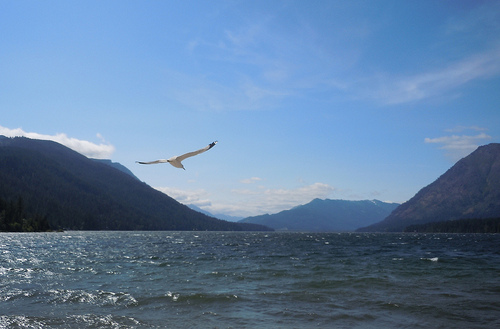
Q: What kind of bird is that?
A: A seagull.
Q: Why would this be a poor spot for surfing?
A: The waves are very small.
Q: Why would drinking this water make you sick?
A: It is saltwater.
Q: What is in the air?
A: A bird.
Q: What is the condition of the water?
A: Calm.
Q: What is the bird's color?
A: White.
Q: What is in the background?
A: Mountains.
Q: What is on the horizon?
A: Mountain.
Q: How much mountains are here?
A: Three.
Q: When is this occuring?
A: During the day time.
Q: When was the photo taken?
A: During the daytime.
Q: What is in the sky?
A: Clouds.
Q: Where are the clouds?
A: In the sky.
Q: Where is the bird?
A: Above the water.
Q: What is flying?
A: The bird.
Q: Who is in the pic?
A: No one.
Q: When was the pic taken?
A: During the day.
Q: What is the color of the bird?
A: White.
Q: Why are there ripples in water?
A: There is movement.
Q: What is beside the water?
A: Hills.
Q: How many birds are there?
A: 1.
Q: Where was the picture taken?
A: Ocean.